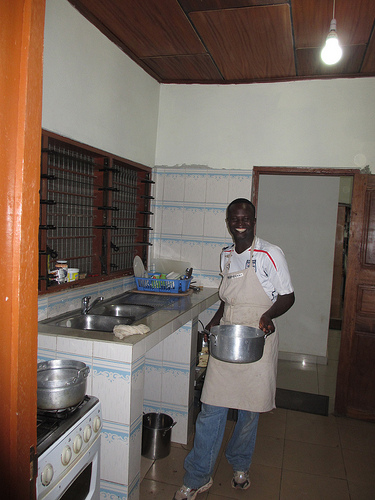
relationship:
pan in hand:
[211, 323, 263, 364] [259, 320, 278, 337]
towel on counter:
[114, 319, 149, 340] [49, 281, 211, 348]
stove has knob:
[40, 360, 111, 500] [71, 430, 84, 455]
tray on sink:
[135, 261, 199, 295] [78, 294, 154, 333]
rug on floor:
[140, 460, 177, 498] [118, 385, 373, 499]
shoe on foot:
[230, 466, 254, 491] [233, 466, 249, 498]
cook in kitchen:
[182, 191, 287, 495] [7, 6, 374, 494]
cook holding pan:
[182, 191, 287, 495] [211, 323, 263, 364]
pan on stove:
[211, 323, 263, 364] [40, 360, 111, 500]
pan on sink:
[211, 323, 263, 364] [78, 294, 154, 333]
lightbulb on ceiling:
[312, 30, 346, 67] [87, 1, 373, 87]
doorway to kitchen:
[250, 170, 351, 407] [7, 6, 374, 494]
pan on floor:
[211, 323, 263, 364] [118, 385, 373, 499]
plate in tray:
[129, 255, 154, 285] [135, 261, 199, 295]